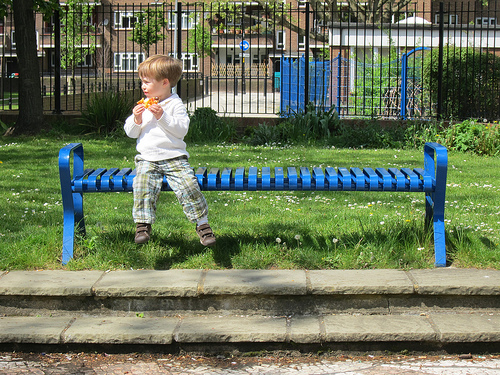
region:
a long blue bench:
[50, 143, 450, 273]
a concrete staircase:
[7, 263, 497, 348]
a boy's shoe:
[192, 225, 222, 245]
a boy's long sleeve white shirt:
[125, 89, 192, 151]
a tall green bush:
[421, 43, 498, 117]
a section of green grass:
[0, 133, 498, 268]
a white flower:
[291, 228, 301, 243]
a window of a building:
[113, 53, 144, 75]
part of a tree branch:
[8, 0, 56, 130]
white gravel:
[203, 355, 498, 374]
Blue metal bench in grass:
[50, 141, 447, 267]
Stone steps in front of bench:
[7, 269, 498, 356]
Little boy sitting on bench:
[120, 56, 225, 245]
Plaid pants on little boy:
[129, 154, 215, 225]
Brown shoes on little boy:
[130, 221, 217, 244]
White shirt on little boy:
[124, 97, 190, 159]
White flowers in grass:
[5, 175, 49, 212]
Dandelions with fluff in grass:
[272, 230, 342, 250]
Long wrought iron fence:
[40, 1, 498, 116]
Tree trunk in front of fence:
[12, 3, 39, 123]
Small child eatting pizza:
[109, 45, 219, 257]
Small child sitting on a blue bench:
[122, 45, 226, 262]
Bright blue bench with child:
[27, 124, 462, 263]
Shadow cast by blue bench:
[108, 215, 495, 266]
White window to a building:
[109, 6, 161, 36]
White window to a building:
[110, 50, 147, 79]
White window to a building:
[154, 43, 215, 83]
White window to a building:
[159, 7, 203, 38]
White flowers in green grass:
[265, 222, 342, 256]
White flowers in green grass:
[454, 163, 492, 249]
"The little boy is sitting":
[101, 48, 250, 269]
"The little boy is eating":
[117, 47, 207, 226]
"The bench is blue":
[51, 124, 490, 275]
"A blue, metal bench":
[49, 132, 479, 274]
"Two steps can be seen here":
[0, 269, 499, 359]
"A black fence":
[1, 8, 498, 134]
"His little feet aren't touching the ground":
[118, 50, 233, 288]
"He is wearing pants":
[107, 46, 236, 265]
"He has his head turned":
[120, 41, 258, 287]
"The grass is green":
[0, 109, 498, 277]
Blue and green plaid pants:
[117, 160, 214, 224]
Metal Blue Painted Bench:
[197, 160, 467, 256]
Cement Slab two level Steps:
[4, 259, 499, 350]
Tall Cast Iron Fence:
[2, 2, 498, 139]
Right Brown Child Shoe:
[123, 222, 155, 243]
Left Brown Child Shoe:
[188, 223, 218, 245]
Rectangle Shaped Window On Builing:
[110, 10, 142, 28]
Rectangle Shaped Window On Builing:
[166, 12, 203, 30]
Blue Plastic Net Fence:
[277, 43, 432, 120]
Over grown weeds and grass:
[271, 220, 487, 260]